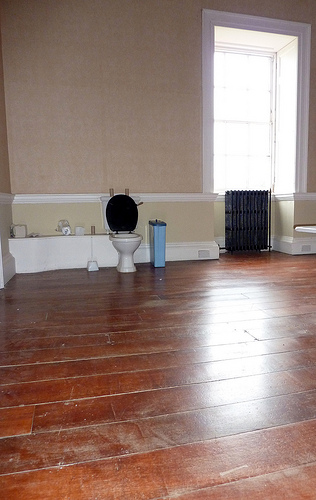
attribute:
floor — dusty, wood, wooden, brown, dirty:
[0, 250, 315, 498]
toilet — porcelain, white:
[100, 195, 143, 274]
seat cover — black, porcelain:
[106, 195, 140, 233]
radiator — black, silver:
[223, 188, 272, 251]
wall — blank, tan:
[0, 1, 316, 259]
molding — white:
[2, 192, 316, 207]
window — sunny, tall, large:
[214, 40, 278, 195]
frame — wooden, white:
[199, 8, 313, 195]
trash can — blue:
[147, 220, 168, 268]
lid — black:
[149, 218, 169, 228]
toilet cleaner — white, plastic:
[86, 233, 100, 272]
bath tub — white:
[294, 225, 315, 235]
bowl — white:
[110, 232, 144, 255]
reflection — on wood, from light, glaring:
[200, 275, 273, 426]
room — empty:
[2, 1, 316, 500]